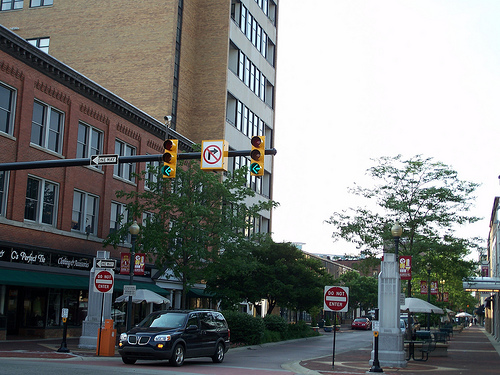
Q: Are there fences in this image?
A: No, there are no fences.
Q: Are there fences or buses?
A: No, there are no fences or buses.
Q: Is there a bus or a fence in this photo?
A: No, there are no fences or buses.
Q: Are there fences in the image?
A: No, there are no fences.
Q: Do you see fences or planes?
A: No, there are no fences or planes.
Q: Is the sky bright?
A: Yes, the sky is bright.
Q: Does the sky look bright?
A: Yes, the sky is bright.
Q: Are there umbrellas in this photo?
A: Yes, there is an umbrella.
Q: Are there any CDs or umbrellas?
A: Yes, there is an umbrella.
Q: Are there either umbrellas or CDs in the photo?
A: Yes, there is an umbrella.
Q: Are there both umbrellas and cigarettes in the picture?
A: No, there is an umbrella but no cigarettes.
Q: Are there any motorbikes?
A: No, there are no motorbikes.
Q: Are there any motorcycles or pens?
A: No, there are no motorcycles or pens.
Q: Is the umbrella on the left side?
A: Yes, the umbrella is on the left of the image.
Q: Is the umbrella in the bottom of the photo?
A: Yes, the umbrella is in the bottom of the image.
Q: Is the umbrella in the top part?
A: No, the umbrella is in the bottom of the image.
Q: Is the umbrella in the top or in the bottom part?
A: The umbrella is in the bottom of the image.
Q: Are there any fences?
A: No, there are no fences.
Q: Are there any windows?
A: Yes, there is a window.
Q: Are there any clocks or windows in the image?
A: Yes, there is a window.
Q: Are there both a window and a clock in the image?
A: No, there is a window but no clocks.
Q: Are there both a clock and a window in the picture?
A: No, there is a window but no clocks.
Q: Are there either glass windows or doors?
A: Yes, there is a glass window.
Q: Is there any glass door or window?
A: Yes, there is a glass window.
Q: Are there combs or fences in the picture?
A: No, there are no fences or combs.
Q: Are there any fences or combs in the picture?
A: No, there are no fences or combs.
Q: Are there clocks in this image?
A: No, there are no clocks.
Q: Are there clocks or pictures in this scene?
A: No, there are no clocks or pictures.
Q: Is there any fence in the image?
A: No, there are no fences.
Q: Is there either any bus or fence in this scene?
A: No, there are no fences or buses.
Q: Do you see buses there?
A: No, there are no buses.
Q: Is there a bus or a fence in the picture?
A: No, there are no buses or fences.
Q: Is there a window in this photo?
A: Yes, there is a window.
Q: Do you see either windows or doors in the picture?
A: Yes, there is a window.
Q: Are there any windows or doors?
A: Yes, there is a window.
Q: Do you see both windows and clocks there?
A: No, there is a window but no clocks.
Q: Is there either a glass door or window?
A: Yes, there is a glass window.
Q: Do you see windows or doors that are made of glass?
A: Yes, the window is made of glass.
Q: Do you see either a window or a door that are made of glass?
A: Yes, the window is made of glass.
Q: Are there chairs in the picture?
A: No, there are no chairs.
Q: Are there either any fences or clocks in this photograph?
A: No, there are no clocks or fences.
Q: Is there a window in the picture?
A: Yes, there is a window.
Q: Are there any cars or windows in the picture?
A: Yes, there is a window.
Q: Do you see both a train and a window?
A: No, there is a window but no trains.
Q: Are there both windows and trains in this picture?
A: No, there is a window but no trains.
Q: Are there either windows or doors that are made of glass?
A: Yes, the window is made of glass.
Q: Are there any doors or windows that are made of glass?
A: Yes, the window is made of glass.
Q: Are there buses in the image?
A: No, there are no buses.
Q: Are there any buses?
A: No, there are no buses.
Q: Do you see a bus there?
A: No, there are no buses.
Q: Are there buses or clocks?
A: No, there are no buses or clocks.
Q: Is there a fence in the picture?
A: No, there are no fences.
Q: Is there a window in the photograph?
A: Yes, there is a window.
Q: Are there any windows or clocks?
A: Yes, there is a window.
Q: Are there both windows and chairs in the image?
A: No, there is a window but no chairs.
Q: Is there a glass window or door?
A: Yes, there is a glass window.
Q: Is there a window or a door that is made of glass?
A: Yes, the window is made of glass.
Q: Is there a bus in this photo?
A: No, there are no buses.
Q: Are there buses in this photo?
A: No, there are no buses.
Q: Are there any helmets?
A: No, there are no helmets.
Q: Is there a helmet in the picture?
A: No, there are no helmets.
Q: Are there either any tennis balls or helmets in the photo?
A: No, there are no helmets or tennis balls.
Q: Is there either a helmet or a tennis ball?
A: No, there are no helmets or tennis balls.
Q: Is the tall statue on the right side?
A: Yes, the statue is on the right of the image.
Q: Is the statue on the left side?
A: No, the statue is on the right of the image.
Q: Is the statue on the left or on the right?
A: The statue is on the right of the image.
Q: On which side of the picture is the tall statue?
A: The statue is on the right of the image.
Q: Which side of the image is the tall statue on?
A: The statue is on the right of the image.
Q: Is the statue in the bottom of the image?
A: Yes, the statue is in the bottom of the image.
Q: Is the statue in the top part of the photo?
A: No, the statue is in the bottom of the image.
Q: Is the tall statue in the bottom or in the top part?
A: The statue is in the bottom of the image.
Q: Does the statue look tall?
A: Yes, the statue is tall.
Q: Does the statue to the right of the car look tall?
A: Yes, the statue is tall.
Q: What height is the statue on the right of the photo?
A: The statue is tall.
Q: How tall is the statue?
A: The statue is tall.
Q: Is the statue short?
A: No, the statue is tall.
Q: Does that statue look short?
A: No, the statue is tall.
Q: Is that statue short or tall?
A: The statue is tall.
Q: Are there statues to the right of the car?
A: Yes, there is a statue to the right of the car.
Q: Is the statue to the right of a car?
A: Yes, the statue is to the right of a car.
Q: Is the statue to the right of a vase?
A: No, the statue is to the right of a car.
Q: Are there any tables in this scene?
A: Yes, there is a table.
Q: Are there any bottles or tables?
A: Yes, there is a table.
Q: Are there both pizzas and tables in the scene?
A: No, there is a table but no pizzas.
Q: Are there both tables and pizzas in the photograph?
A: No, there is a table but no pizzas.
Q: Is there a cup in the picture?
A: No, there are no cups.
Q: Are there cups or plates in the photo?
A: No, there are no cups or plates.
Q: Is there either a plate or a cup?
A: No, there are no cups or plates.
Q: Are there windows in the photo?
A: Yes, there is a window.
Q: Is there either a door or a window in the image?
A: Yes, there is a window.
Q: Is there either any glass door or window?
A: Yes, there is a glass window.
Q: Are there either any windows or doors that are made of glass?
A: Yes, the window is made of glass.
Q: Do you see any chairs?
A: No, there are no chairs.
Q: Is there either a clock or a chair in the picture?
A: No, there are no chairs or clocks.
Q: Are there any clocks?
A: No, there are no clocks.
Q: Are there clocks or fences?
A: No, there are no clocks or fences.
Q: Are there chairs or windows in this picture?
A: Yes, there is a window.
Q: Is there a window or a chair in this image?
A: Yes, there is a window.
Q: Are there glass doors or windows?
A: Yes, there is a glass window.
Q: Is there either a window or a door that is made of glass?
A: Yes, the window is made of glass.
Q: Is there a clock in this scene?
A: No, there are no clocks.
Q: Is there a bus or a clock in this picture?
A: No, there are no clocks or buses.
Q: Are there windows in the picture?
A: Yes, there is a window.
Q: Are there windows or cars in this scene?
A: Yes, there is a window.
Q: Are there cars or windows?
A: Yes, there is a window.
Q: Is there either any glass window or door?
A: Yes, there is a glass window.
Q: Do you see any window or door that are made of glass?
A: Yes, the window is made of glass.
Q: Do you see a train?
A: No, there are no trains.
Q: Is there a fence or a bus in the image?
A: No, there are no fences or buses.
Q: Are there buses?
A: No, there are no buses.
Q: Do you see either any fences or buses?
A: No, there are no buses or fences.